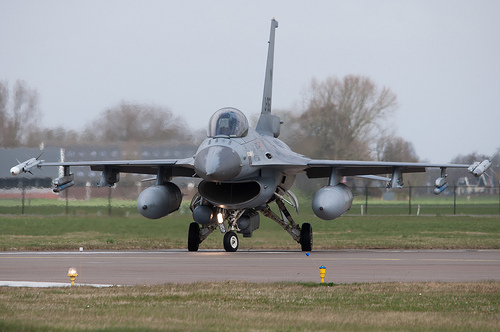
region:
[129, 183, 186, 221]
long missal on plane wing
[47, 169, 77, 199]
long missal on plane wing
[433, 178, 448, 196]
long missal on plane wing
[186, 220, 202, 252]
round black colored tire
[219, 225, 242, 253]
round black colored tire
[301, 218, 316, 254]
round black colored tire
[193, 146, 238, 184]
grey colored plane nose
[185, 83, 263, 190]
cockpit of a plane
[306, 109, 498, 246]
wings of a plane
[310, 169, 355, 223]
missile of a plane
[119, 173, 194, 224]
missile of a plane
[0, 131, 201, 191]
wings of a plane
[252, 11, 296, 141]
back wing of a plane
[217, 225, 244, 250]
wheel of a plane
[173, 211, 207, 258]
wheel of a plane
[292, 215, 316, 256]
wheel of a plane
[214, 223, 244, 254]
part on fighter jet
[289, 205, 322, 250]
part on fighter jet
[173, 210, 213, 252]
part on fighter jet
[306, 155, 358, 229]
part on fighter jet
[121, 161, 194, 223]
part on fighter jet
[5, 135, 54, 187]
part on fighter jet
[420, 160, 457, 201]
part on fighter jet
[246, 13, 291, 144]
part on fighter jet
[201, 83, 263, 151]
part on fighter jet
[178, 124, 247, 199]
part on fighter jet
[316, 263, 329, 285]
Small yellow post with a blue light mounted on top of it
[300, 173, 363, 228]
One engine of the plane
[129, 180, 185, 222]
One engine of the plane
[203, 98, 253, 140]
Top window of the plane cockpit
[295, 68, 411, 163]
Tree in the background behind the plane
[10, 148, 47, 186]
Edge of the plane wing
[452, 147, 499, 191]
Edge of the plane wing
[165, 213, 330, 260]
Three black plane wheels on the runway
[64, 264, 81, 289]
Small yellow post with a white light on top of it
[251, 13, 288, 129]
Tall tail wing of the plane